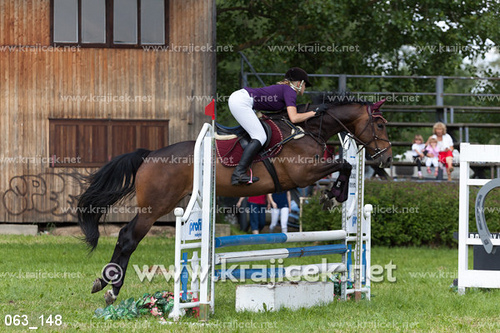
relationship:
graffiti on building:
[0, 162, 111, 216] [2, 2, 219, 223]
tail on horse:
[78, 145, 152, 257] [90, 89, 392, 307]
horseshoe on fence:
[472, 176, 500, 256] [455, 139, 500, 299]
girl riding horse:
[228, 67, 329, 185] [90, 89, 392, 307]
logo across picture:
[134, 258, 398, 284] [6, 1, 500, 331]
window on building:
[47, 2, 167, 46] [2, 2, 219, 223]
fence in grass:
[455, 139, 500, 299] [5, 233, 500, 328]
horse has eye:
[90, 89, 392, 307] [378, 121, 386, 128]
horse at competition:
[90, 89, 392, 307] [5, 5, 498, 329]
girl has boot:
[223, 65, 325, 185] [231, 139, 261, 186]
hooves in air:
[326, 185, 348, 207] [7, 8, 500, 322]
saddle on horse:
[211, 111, 301, 170] [90, 89, 392, 307]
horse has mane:
[90, 89, 392, 307] [301, 86, 380, 115]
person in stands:
[427, 122, 455, 181] [242, 64, 500, 194]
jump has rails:
[163, 118, 376, 317] [214, 225, 346, 279]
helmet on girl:
[286, 66, 314, 83] [228, 67, 329, 185]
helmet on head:
[286, 66, 314, 83] [284, 66, 318, 97]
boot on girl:
[234, 138, 261, 185] [228, 67, 329, 185]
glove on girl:
[315, 102, 329, 118] [228, 67, 329, 185]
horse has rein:
[90, 89, 392, 307] [305, 108, 396, 169]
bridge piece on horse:
[370, 138, 394, 161] [90, 89, 392, 307]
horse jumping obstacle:
[90, 89, 392, 307] [164, 120, 376, 327]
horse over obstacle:
[90, 89, 392, 307] [164, 120, 376, 327]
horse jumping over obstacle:
[90, 89, 392, 307] [164, 120, 376, 327]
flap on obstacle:
[172, 124, 207, 312] [164, 120, 376, 327]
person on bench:
[427, 122, 455, 181] [380, 152, 469, 171]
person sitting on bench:
[427, 122, 455, 181] [380, 152, 469, 171]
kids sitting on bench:
[409, 134, 442, 173] [380, 152, 469, 171]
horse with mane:
[90, 89, 392, 307] [301, 86, 380, 115]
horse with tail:
[90, 89, 392, 307] [78, 145, 152, 257]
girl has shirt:
[228, 67, 329, 185] [246, 84, 296, 110]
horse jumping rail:
[90, 89, 392, 307] [215, 223, 352, 250]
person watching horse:
[430, 121, 455, 171] [90, 89, 392, 307]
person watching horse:
[427, 122, 455, 181] [90, 89, 392, 307]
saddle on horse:
[215, 119, 272, 185] [90, 89, 392, 307]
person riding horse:
[427, 122, 455, 181] [90, 89, 392, 307]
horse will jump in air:
[90, 89, 392, 307] [7, 8, 500, 322]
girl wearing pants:
[228, 67, 329, 185] [224, 90, 271, 147]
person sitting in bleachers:
[427, 122, 455, 181] [241, 53, 499, 174]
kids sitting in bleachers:
[409, 134, 442, 173] [241, 53, 499, 174]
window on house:
[47, 2, 167, 46] [3, 4, 219, 219]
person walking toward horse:
[269, 193, 296, 232] [90, 89, 392, 307]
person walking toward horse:
[236, 192, 279, 237] [90, 89, 392, 307]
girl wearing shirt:
[228, 67, 329, 185] [246, 84, 296, 110]